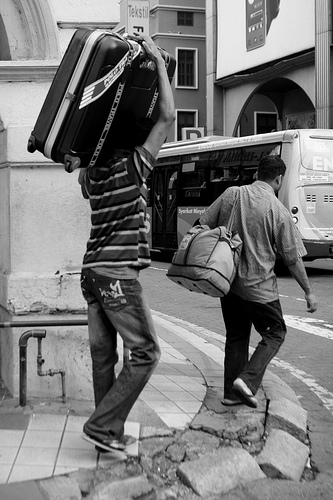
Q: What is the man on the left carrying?
A: A suitcase.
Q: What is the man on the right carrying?
A: A large bag.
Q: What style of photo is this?
A: Black and white.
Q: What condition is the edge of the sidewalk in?
A: Crumbling.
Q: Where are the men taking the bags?
A: To the bus.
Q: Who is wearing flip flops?
A: The man on the right.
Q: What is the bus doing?
A: It is parked.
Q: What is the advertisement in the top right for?
A: A cell phone.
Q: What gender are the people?
A: Male.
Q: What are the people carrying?
A: Luggage.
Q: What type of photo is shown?
A: Black and white.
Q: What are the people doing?
A: Walking.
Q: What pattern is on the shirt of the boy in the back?
A: Stripes.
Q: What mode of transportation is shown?
A: Bus.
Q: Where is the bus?
A: Road.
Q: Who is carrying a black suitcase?
A: A man.